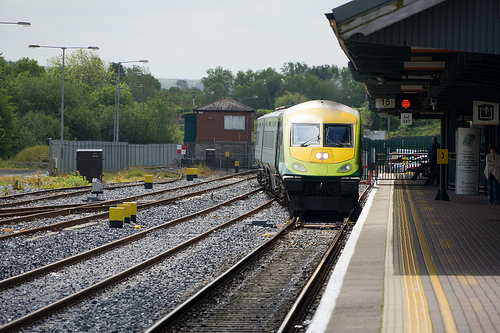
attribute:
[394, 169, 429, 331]
line — painted , yellow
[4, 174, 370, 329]
rails — railroad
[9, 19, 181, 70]
lights — off, street 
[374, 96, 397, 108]
sign — white 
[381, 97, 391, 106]
black number — black  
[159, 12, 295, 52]
sky — clear , area 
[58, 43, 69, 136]
pole — one 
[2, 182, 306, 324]
tracks — Many 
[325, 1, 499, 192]
station — train 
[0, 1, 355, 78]
sky — gray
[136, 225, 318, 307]
train tracks — metal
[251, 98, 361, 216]
train — yellow, black, yellow front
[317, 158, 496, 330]
platform — train loading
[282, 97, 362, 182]
front — green 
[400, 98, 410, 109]
light — on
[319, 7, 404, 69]
roof — thick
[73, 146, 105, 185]
electrical box — outdoor electrical 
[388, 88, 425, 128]
light — red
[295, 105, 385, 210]
train — yellow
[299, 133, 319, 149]
wiper — black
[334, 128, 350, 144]
wiper — black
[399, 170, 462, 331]
line — yellow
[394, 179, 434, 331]
line — yellow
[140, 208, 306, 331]
rail — metal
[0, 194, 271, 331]
rail — metal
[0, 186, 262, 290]
rail — metal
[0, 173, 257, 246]
rail — metal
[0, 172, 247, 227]
rail — metal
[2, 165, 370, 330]
ground — gravel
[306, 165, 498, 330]
platform — striped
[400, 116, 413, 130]
signs — small , large 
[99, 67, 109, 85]
leaves — green  